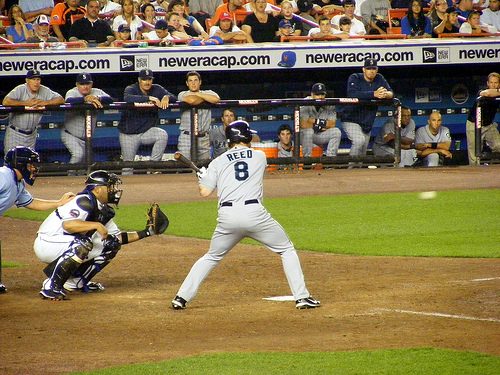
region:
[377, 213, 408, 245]
the grass is green in color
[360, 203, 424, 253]
the grass is short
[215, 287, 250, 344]
this is the ground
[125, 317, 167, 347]
the ground has sand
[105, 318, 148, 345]
the sand is brown in color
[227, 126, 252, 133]
this is the helmet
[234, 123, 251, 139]
the helmet is black in color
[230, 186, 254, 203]
the t-shirt is white in color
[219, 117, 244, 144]
man has black helmet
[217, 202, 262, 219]
man has black belt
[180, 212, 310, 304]
man has grey pants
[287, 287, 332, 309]
black and white shoes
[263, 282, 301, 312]
home plate is white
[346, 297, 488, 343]
white lines on dirt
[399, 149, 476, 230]
baseball is in air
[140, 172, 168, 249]
catcher has black gloves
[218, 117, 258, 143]
the helmet is blue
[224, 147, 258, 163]
reed is the name of the player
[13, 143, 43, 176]
the helemet is blue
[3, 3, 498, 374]
the game is baseball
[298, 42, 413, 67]
the website is newercap.com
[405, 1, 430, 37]
the woman has glases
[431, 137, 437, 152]
the band is black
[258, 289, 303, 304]
flat white home plate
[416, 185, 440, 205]
globular white baseball in the air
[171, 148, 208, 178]
brown wooden baseball bat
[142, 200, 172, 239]
thick brown catcher's glove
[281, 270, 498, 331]
white chalk lines around baseball diamond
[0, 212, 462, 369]
circular brown dirt batter's box area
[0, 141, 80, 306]
umpire wearing light blue shirt and dark blue mask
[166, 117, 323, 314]
baseball batter swinging at baseball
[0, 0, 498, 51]
fans in stands watching baseball game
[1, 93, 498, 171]
black padded railing around dugout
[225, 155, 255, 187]
Number "8" on back of a shirt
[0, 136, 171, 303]
Umpire has his hand on the catcher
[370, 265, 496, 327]
White lines on the dirt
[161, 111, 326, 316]
The batter is holding a bat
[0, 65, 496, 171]
Baseball players in the dugout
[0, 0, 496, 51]
Spectators watching the game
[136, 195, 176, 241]
A black leather glove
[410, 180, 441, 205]
A white baseball in the air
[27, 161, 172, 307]
A catcher is crouched down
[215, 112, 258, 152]
A helmet is black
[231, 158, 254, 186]
number on the jersey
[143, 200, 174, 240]
a catchers mit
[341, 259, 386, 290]
dirt is brown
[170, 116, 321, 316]
a person is playing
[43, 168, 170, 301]
a person is playing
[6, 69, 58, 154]
a person is standing up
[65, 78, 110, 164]
a person is standing up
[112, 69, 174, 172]
a person is standing up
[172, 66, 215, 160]
a person is standing up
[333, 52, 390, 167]
a person is standing up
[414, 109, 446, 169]
a person is sitting down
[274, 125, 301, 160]
a person is sitting down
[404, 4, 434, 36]
a person is sitting down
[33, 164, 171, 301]
catcher is bent over behind the plate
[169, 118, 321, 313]
baseball player swings the bat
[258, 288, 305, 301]
home plate is in front of the batter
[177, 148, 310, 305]
uniform is worn by the batter